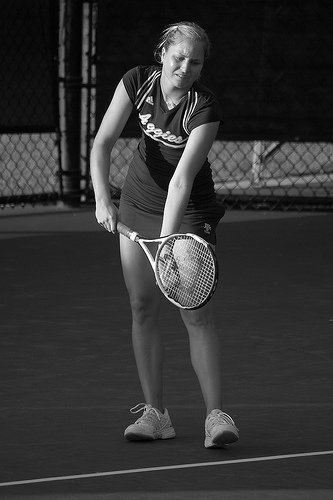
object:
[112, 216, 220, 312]
racket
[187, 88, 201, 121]
stripes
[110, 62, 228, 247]
dress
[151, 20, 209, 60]
light hair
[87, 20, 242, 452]
girl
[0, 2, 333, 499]
picture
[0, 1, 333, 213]
fence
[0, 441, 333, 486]
line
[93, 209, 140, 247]
handle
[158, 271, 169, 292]
ball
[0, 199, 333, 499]
tennis court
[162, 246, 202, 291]
logo